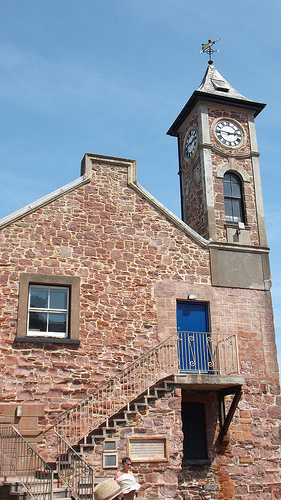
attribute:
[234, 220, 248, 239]
camera — security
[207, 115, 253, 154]
clock — white, black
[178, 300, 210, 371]
door — blue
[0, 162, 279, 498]
wall — rustic, brick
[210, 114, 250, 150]
white clock —  analog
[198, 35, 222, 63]
vane — on top, for weather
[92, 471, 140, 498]
hats — light 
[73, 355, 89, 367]
stone — building's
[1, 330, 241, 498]
railing — metal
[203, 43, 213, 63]
rod — lightning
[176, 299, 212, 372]
door — blue, at upper level 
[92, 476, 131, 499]
hat — cream color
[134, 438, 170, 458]
sign — illegible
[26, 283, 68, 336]
window — white, crystal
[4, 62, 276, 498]
building — cobblestone , large, Red , brick, historical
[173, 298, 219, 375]
door — Single, blue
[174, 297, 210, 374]
door — crystal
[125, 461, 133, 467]
sunglasses — Woman's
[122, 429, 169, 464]
sign — white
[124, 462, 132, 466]
sunglasses — black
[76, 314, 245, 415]
rail —   is along stairs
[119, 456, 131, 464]
hair — short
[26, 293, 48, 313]
reflection — of  tree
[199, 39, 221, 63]
cross — Metal 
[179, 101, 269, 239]
building — cobblestone 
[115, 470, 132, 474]
shirt — pink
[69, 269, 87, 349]
framing — stone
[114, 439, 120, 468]
framing — wood